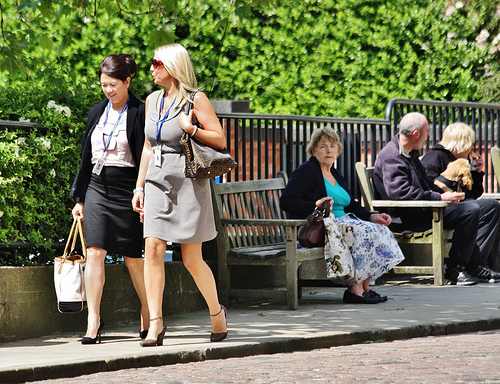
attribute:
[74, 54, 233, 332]
women — walking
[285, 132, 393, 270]
woman — old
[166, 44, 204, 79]
hair — blonde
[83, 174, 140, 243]
skirt — black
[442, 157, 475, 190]
dog — brown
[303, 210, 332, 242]
bag — black, brown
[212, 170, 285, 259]
bench — brown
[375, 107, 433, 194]
man — old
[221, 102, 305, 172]
railing — black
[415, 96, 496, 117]
fence — black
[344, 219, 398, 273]
skirt — blue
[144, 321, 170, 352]
shoe — black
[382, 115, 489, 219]
people — sitting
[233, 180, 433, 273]
benches — brown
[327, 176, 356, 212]
shirt — blue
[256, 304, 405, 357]
sidewalk — grey